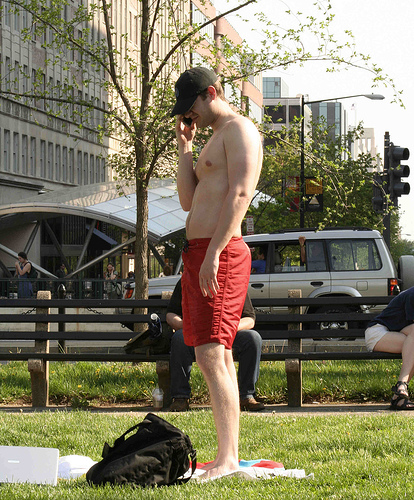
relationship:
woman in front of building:
[94, 261, 145, 311] [20, 48, 174, 168]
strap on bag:
[172, 441, 213, 493] [73, 397, 222, 498]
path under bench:
[0, 409, 414, 420] [4, 289, 412, 404]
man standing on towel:
[170, 65, 264, 482] [175, 458, 315, 485]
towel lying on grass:
[178, 458, 315, 484] [227, 479, 359, 497]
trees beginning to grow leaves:
[9, 4, 387, 238] [63, 9, 378, 227]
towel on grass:
[178, 458, 315, 484] [3, 356, 409, 494]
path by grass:
[79, 386, 398, 432] [290, 412, 383, 484]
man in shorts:
[170, 65, 264, 482] [179, 232, 251, 350]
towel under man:
[187, 453, 310, 484] [170, 65, 264, 482]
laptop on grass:
[0, 442, 65, 482] [1, 344, 411, 498]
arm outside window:
[297, 244, 305, 264] [272, 239, 307, 269]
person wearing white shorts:
[336, 274, 412, 391] [337, 306, 411, 358]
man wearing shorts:
[155, 208, 291, 382] [177, 220, 304, 350]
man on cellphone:
[170, 65, 264, 482] [171, 96, 191, 137]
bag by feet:
[102, 399, 210, 483] [172, 395, 313, 482]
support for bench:
[285, 288, 302, 405] [10, 261, 127, 384]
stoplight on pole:
[374, 120, 412, 220] [373, 116, 400, 298]